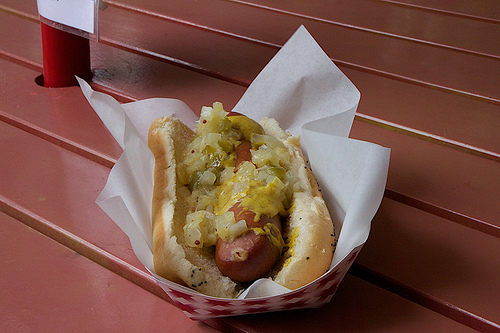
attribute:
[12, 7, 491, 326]
table — red, plastic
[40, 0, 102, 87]
pole — red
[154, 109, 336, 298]
hot dog — red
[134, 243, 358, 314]
tray — paper, red, white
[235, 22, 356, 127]
paper — white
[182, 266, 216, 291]
seeds — poppy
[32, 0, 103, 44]
sign — white